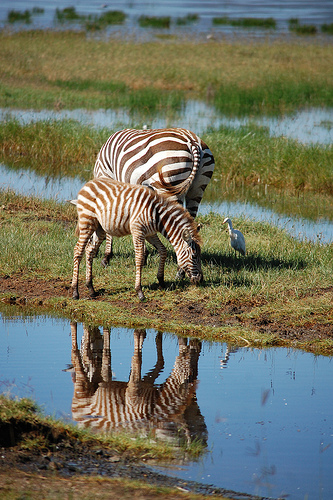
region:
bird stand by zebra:
[218, 212, 270, 265]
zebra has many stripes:
[63, 187, 211, 314]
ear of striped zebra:
[170, 227, 213, 238]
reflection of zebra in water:
[27, 318, 207, 496]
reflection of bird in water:
[225, 351, 234, 368]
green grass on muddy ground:
[7, 230, 268, 302]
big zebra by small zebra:
[80, 104, 219, 296]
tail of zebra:
[74, 202, 91, 237]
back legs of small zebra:
[60, 274, 98, 320]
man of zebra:
[148, 194, 210, 236]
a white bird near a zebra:
[216, 213, 257, 267]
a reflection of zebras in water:
[46, 306, 211, 476]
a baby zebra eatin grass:
[61, 172, 205, 294]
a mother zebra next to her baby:
[86, 122, 220, 273]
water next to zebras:
[0, 298, 331, 498]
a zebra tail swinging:
[148, 133, 202, 204]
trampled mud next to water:
[11, 269, 256, 326]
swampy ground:
[3, 8, 328, 225]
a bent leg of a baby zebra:
[146, 236, 182, 288]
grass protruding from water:
[133, 12, 175, 28]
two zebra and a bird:
[67, 117, 257, 308]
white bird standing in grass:
[215, 215, 253, 268]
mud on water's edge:
[77, 449, 156, 479]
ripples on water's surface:
[203, 350, 281, 375]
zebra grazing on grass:
[171, 269, 225, 290]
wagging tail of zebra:
[153, 140, 204, 206]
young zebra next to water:
[63, 178, 210, 338]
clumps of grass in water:
[180, 6, 302, 35]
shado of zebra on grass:
[198, 248, 302, 277]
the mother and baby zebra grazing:
[66, 126, 217, 305]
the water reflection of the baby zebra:
[62, 314, 211, 465]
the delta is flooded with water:
[5, 1, 330, 494]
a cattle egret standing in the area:
[218, 209, 255, 263]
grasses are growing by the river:
[4, 3, 331, 123]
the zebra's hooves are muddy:
[64, 247, 171, 304]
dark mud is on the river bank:
[24, 433, 233, 499]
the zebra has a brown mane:
[157, 192, 201, 241]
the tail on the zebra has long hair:
[149, 138, 199, 199]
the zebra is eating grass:
[169, 223, 210, 291]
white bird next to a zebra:
[216, 211, 252, 261]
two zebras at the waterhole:
[60, 116, 218, 305]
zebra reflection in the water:
[57, 308, 229, 474]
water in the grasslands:
[32, 83, 69, 207]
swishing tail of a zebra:
[157, 141, 208, 199]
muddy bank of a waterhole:
[11, 408, 142, 488]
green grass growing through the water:
[8, 2, 323, 47]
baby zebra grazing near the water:
[67, 176, 209, 305]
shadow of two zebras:
[204, 245, 302, 300]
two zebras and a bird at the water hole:
[29, 78, 264, 331]